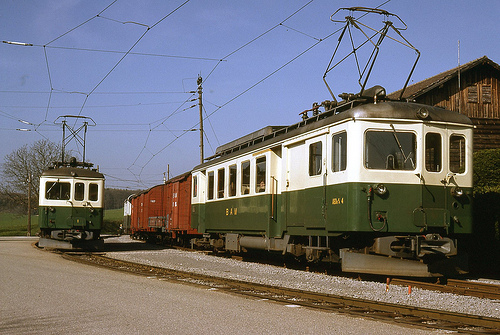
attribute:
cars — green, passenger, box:
[197, 137, 388, 225]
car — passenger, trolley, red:
[138, 173, 186, 230]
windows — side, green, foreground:
[217, 156, 283, 186]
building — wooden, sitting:
[425, 68, 490, 101]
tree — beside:
[10, 151, 52, 201]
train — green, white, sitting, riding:
[53, 163, 316, 232]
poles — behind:
[183, 69, 215, 137]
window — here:
[36, 175, 115, 220]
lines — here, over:
[76, 29, 201, 127]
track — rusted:
[418, 267, 482, 300]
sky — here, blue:
[145, 25, 247, 117]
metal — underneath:
[222, 227, 322, 275]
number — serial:
[320, 183, 362, 199]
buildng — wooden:
[425, 72, 499, 132]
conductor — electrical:
[329, 14, 394, 80]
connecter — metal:
[409, 232, 457, 263]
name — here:
[216, 199, 244, 224]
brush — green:
[11, 214, 47, 244]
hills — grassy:
[95, 196, 125, 223]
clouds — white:
[138, 126, 182, 178]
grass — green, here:
[12, 210, 32, 227]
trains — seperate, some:
[49, 143, 323, 254]